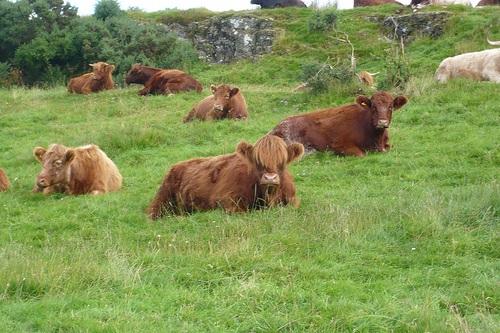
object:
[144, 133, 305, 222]
cow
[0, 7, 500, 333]
grass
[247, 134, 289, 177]
thick hair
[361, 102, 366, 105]
tag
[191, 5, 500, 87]
ledge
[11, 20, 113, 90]
bushes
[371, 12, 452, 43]
rock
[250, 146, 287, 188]
face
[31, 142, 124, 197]
animals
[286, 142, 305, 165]
ear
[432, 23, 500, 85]
cow